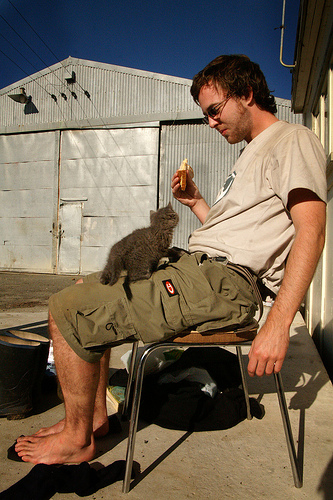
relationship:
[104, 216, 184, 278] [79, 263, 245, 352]
kitty on lap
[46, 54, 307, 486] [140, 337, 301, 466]
man on chair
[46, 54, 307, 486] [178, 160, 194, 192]
man holding sandwich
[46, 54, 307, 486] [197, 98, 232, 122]
man wearing glasses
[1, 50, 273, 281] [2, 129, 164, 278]
building has door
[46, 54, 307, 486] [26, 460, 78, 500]
man cast shadow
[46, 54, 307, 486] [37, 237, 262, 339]
man wearing shorts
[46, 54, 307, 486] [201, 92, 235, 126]
man wearing glasses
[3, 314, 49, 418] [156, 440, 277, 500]
boot on ground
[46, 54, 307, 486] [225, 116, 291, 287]
man wearing shirt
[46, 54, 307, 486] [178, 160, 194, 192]
man eating sandwich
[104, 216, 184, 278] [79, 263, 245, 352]
kitty in lap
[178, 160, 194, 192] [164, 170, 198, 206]
sandwich in hand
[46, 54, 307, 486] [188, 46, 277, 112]
man has hair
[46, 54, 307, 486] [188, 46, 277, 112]
man with hair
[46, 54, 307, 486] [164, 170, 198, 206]
man has hand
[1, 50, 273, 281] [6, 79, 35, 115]
building has light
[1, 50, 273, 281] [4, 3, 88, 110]
building has wires